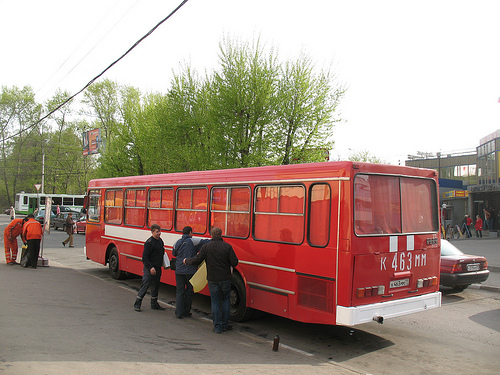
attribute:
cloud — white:
[156, 0, 493, 159]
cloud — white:
[0, 0, 105, 137]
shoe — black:
[149, 300, 169, 311]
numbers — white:
[387, 246, 425, 280]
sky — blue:
[3, 2, 498, 109]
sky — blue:
[259, 10, 284, 28]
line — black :
[0, 0, 185, 142]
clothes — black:
[133, 235, 167, 311]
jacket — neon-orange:
[22, 220, 42, 240]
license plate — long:
[388, 277, 410, 288]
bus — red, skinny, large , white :
[84, 159, 441, 337]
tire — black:
[104, 247, 120, 273]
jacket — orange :
[23, 210, 43, 242]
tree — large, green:
[133, 40, 343, 165]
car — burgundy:
[435, 233, 495, 300]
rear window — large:
[349, 166, 446, 245]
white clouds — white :
[362, 67, 444, 137]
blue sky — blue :
[3, 0, 498, 164]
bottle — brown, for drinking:
[268, 330, 284, 352]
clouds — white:
[34, 33, 480, 92]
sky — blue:
[17, 0, 499, 154]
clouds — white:
[35, 6, 97, 60]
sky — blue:
[8, 0, 498, 135]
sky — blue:
[0, 1, 498, 167]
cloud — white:
[380, 29, 410, 68]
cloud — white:
[232, 7, 289, 48]